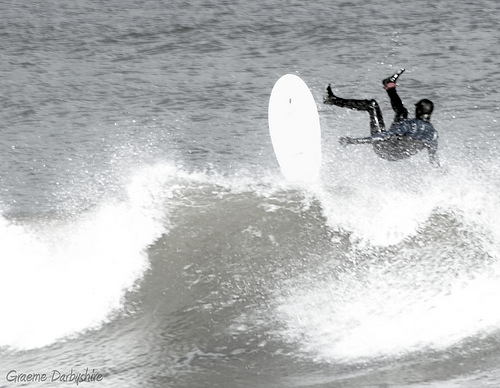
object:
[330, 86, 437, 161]
wet suit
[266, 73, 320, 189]
surfboard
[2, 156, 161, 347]
wave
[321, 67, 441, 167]
man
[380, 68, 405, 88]
foot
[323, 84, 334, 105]
left foot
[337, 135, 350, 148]
left hand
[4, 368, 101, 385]
phographer's name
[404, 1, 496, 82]
waves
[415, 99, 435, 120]
head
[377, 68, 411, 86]
right foot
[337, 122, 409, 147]
left arm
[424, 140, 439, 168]
right arm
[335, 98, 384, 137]
left leg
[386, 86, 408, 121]
rigth leg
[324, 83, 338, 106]
shoes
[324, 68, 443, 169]
person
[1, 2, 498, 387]
ocean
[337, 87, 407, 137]
pants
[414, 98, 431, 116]
wet hair